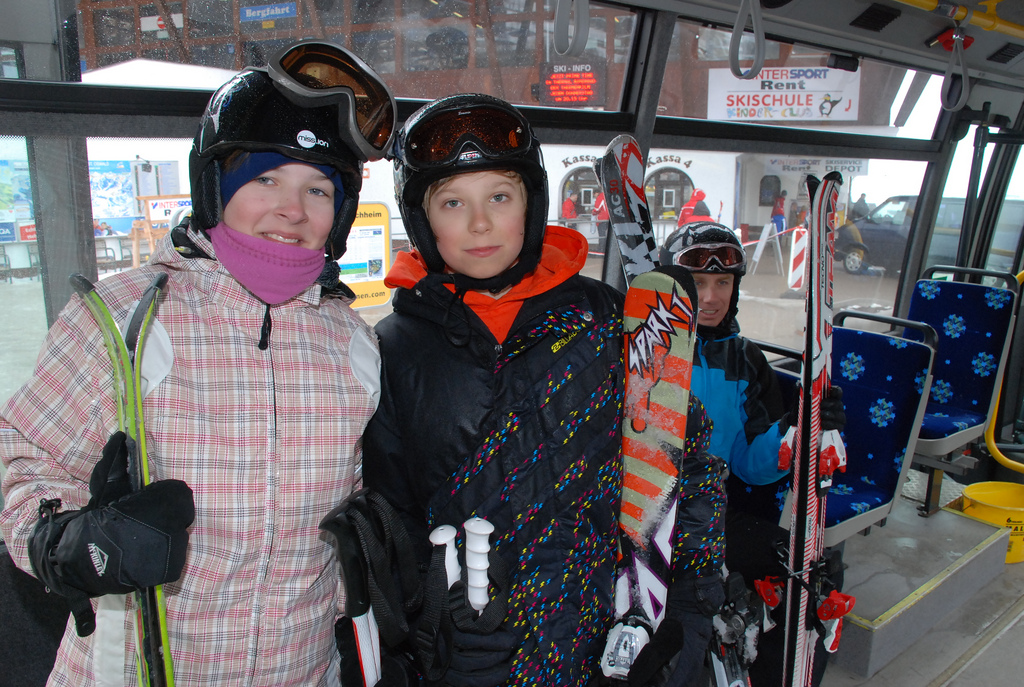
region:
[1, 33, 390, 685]
woman wearing pink plaid jacket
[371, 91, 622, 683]
woman wearing black jacket with spots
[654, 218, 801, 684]
man wearing blue and black jacket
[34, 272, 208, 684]
green skis held by black glove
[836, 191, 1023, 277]
black van parked next to building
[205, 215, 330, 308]
pink knitted scarf on face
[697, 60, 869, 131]
white sign with red letters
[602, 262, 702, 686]
ski with orange stripes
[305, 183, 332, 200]
a woman's left eye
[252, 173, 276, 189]
a woman's right eye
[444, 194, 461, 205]
a boy's right eye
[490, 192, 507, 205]
a boy's left eye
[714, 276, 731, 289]
a man's left eye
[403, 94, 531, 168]
a pair of snow goggles with amber lenses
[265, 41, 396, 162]
a pair of snow goggles with amber lenses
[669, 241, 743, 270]
a pair of snow goggles with amber lenses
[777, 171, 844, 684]
a pair of men's skis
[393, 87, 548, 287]
a black helmet on woman's head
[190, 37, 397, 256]
gray ski goggle on top of black helmet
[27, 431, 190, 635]
black ski gloves with a white logo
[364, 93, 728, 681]
woman holding white ski poles and orange skis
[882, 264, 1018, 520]
a blue stuffed bus chair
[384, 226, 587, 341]
an orange sweater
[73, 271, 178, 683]
green lime skis with black tip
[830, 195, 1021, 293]
a parked black van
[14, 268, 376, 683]
a jacket that is pink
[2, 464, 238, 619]
a glove that is black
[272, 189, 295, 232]
the nose of a woman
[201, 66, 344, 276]
the head of a woman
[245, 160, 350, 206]
the eye of a woman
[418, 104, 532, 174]
the goggles of a woman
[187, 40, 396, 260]
tilted goggles on black helmet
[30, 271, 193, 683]
mitten holding pair of skis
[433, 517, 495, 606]
white handles of ski poles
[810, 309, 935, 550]
designs on blue seat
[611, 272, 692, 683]
orange stripes on ski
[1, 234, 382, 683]
zippered up plaid jacket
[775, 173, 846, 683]
pair of vertical skis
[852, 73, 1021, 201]
light in daytime sky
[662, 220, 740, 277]
light reflection on black helmet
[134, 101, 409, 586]
a person on a bus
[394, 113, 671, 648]
a person on a bus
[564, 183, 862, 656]
a person on a bus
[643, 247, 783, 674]
a person on a bus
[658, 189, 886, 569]
a person wearing a helmet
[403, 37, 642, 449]
a person wearing a helmet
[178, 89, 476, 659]
a person wearing a helmet